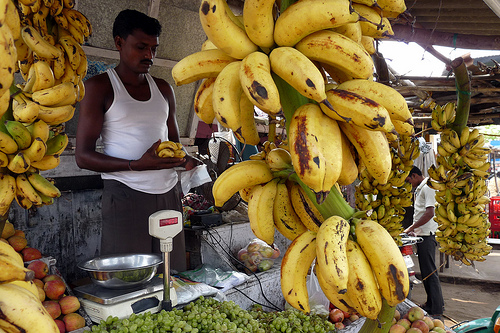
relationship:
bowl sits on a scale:
[61, 249, 174, 300] [103, 303, 155, 333]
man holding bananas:
[97, 23, 178, 278] [148, 146, 208, 186]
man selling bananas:
[75, 11, 208, 277] [186, 9, 418, 266]